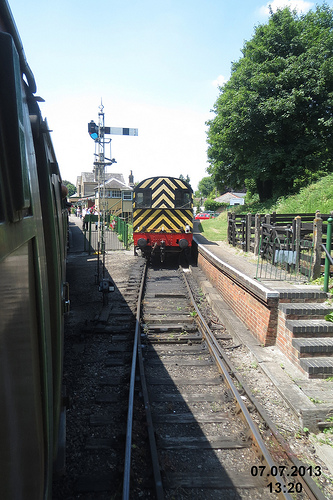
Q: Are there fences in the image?
A: Yes, there is a fence.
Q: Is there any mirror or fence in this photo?
A: Yes, there is a fence.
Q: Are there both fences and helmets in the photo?
A: No, there is a fence but no helmets.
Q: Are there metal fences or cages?
A: Yes, there is a metal fence.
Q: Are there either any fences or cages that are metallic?
A: Yes, the fence is metallic.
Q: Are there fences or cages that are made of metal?
A: Yes, the fence is made of metal.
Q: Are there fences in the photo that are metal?
A: Yes, there is a metal fence.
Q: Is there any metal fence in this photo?
A: Yes, there is a metal fence.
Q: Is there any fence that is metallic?
A: Yes, there is a fence that is metallic.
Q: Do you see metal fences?
A: Yes, there is a fence that is made of metal.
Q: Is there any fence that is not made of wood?
A: Yes, there is a fence that is made of metal.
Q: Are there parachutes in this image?
A: No, there are no parachutes.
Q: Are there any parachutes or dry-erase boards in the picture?
A: No, there are no parachutes or dry-erase boards.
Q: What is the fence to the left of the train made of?
A: The fence is made of metal.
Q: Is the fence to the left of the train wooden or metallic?
A: The fence is metallic.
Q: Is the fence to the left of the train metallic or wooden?
A: The fence is metallic.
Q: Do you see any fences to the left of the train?
A: Yes, there is a fence to the left of the train.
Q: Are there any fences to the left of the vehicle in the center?
A: Yes, there is a fence to the left of the train.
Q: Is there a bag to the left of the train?
A: No, there is a fence to the left of the train.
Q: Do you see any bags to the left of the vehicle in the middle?
A: No, there is a fence to the left of the train.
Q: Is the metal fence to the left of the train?
A: Yes, the fence is to the left of the train.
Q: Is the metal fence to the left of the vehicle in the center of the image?
A: Yes, the fence is to the left of the train.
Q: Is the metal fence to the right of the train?
A: No, the fence is to the left of the train.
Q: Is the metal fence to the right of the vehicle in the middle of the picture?
A: No, the fence is to the left of the train.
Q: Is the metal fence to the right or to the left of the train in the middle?
A: The fence is to the left of the train.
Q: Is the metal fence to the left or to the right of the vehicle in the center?
A: The fence is to the left of the train.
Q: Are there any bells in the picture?
A: No, there are no bells.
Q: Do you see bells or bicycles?
A: No, there are no bells or bicycles.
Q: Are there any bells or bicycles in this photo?
A: No, there are no bells or bicycles.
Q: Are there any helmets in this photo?
A: No, there are no helmets.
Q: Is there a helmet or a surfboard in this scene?
A: No, there are no helmets or surfboards.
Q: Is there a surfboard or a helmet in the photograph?
A: No, there are no helmets or surfboards.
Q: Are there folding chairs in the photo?
A: No, there are no folding chairs.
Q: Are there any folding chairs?
A: No, there are no folding chairs.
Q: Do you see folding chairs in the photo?
A: No, there are no folding chairs.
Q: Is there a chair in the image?
A: No, there are no chairs.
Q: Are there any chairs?
A: No, there are no chairs.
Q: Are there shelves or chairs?
A: No, there are no chairs or shelves.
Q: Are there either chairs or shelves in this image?
A: No, there are no chairs or shelves.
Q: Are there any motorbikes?
A: No, there are no motorbikes.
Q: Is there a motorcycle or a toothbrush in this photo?
A: No, there are no motorcycles or toothbrushes.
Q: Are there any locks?
A: No, there are no locks.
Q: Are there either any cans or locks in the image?
A: No, there are no locks or cans.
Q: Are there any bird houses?
A: No, there are no bird houses.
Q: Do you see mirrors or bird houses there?
A: No, there are no bird houses or mirrors.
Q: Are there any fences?
A: Yes, there is a fence.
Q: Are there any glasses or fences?
A: Yes, there is a fence.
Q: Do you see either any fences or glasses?
A: Yes, there is a fence.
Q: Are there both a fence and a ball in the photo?
A: No, there is a fence but no balls.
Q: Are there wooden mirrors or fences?
A: Yes, there is a wood fence.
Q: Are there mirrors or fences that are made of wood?
A: Yes, the fence is made of wood.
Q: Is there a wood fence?
A: Yes, there is a fence that is made of wood.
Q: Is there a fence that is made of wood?
A: Yes, there is a fence that is made of wood.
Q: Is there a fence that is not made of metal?
A: Yes, there is a fence that is made of wood.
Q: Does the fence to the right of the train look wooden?
A: Yes, the fence is wooden.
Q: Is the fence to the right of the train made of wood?
A: Yes, the fence is made of wood.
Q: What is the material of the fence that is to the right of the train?
A: The fence is made of wood.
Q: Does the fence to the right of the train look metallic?
A: No, the fence is wooden.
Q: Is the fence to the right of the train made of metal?
A: No, the fence is made of wood.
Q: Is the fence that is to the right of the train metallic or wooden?
A: The fence is wooden.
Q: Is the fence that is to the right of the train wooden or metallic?
A: The fence is wooden.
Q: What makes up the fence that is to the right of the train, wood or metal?
A: The fence is made of wood.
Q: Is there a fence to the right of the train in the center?
A: Yes, there is a fence to the right of the train.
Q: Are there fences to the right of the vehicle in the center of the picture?
A: Yes, there is a fence to the right of the train.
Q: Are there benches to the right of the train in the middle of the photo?
A: No, there is a fence to the right of the train.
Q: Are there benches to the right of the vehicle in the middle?
A: No, there is a fence to the right of the train.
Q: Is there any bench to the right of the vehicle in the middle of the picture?
A: No, there is a fence to the right of the train.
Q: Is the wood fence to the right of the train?
A: Yes, the fence is to the right of the train.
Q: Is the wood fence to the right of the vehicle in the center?
A: Yes, the fence is to the right of the train.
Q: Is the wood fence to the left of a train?
A: No, the fence is to the right of a train.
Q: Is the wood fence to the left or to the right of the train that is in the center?
A: The fence is to the right of the train.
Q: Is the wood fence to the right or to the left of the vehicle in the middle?
A: The fence is to the right of the train.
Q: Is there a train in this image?
A: Yes, there is a train.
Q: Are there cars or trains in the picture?
A: Yes, there is a train.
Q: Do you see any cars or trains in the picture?
A: Yes, there is a train.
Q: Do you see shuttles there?
A: No, there are no shuttles.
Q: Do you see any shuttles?
A: No, there are no shuttles.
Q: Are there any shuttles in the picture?
A: No, there are no shuttles.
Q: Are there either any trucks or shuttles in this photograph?
A: No, there are no shuttles or trucks.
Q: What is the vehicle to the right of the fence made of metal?
A: The vehicle is a train.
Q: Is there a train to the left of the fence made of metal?
A: No, the train is to the right of the fence.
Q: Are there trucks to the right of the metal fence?
A: No, there is a train to the right of the fence.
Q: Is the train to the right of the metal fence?
A: Yes, the train is to the right of the fence.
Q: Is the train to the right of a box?
A: No, the train is to the right of the fence.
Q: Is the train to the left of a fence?
A: No, the train is to the right of a fence.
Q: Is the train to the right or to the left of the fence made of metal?
A: The train is to the right of the fence.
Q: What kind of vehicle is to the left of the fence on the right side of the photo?
A: The vehicle is a train.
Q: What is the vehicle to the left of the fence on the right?
A: The vehicle is a train.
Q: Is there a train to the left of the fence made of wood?
A: Yes, there is a train to the left of the fence.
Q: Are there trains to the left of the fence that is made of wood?
A: Yes, there is a train to the left of the fence.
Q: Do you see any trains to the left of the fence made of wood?
A: Yes, there is a train to the left of the fence.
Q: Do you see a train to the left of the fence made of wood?
A: Yes, there is a train to the left of the fence.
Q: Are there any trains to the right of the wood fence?
A: No, the train is to the left of the fence.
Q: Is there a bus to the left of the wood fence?
A: No, there is a train to the left of the fence.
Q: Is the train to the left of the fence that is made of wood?
A: Yes, the train is to the left of the fence.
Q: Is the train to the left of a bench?
A: No, the train is to the left of the fence.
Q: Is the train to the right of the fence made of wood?
A: No, the train is to the left of the fence.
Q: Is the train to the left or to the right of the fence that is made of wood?
A: The train is to the left of the fence.